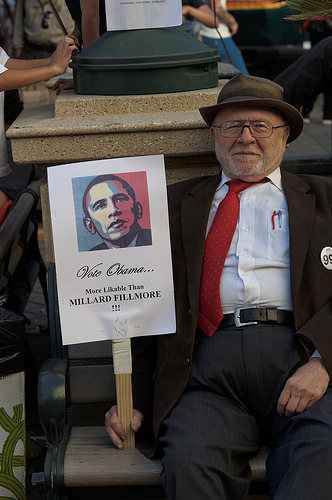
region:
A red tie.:
[195, 180, 251, 331]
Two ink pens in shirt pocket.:
[260, 199, 287, 247]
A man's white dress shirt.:
[212, 175, 290, 305]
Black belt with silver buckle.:
[217, 301, 291, 328]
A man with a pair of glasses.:
[200, 71, 304, 196]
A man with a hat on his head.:
[200, 63, 298, 182]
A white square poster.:
[40, 155, 178, 346]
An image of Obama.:
[66, 165, 161, 311]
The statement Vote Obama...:
[74, 261, 159, 279]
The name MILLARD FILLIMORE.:
[66, 288, 164, 306]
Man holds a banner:
[36, 65, 331, 498]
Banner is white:
[28, 149, 194, 471]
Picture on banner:
[59, 163, 159, 255]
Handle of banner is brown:
[102, 340, 149, 456]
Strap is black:
[221, 301, 292, 329]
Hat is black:
[186, 65, 305, 120]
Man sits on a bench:
[91, 66, 330, 499]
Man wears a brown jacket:
[61, 70, 330, 498]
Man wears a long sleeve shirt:
[84, 59, 331, 498]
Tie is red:
[198, 178, 249, 343]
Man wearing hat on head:
[200, 76, 311, 156]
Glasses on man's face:
[211, 118, 310, 160]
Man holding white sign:
[50, 136, 185, 442]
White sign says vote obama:
[35, 192, 194, 330]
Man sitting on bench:
[106, 354, 329, 470]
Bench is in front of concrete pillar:
[30, 176, 163, 377]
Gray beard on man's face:
[210, 124, 303, 186]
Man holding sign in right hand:
[101, 394, 169, 434]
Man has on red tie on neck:
[210, 166, 305, 333]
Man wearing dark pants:
[158, 385, 310, 488]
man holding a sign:
[105, 72, 331, 499]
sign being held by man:
[46, 153, 177, 345]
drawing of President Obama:
[71, 171, 152, 250]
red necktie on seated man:
[198, 178, 251, 340]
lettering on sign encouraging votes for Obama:
[68, 261, 163, 312]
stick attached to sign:
[112, 337, 137, 451]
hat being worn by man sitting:
[195, 72, 305, 145]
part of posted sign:
[104, 0, 188, 31]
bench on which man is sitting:
[43, 411, 165, 494]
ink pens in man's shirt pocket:
[268, 207, 283, 234]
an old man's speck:
[214, 113, 271, 137]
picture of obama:
[69, 172, 151, 255]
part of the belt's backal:
[233, 303, 280, 322]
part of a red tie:
[209, 222, 221, 282]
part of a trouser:
[233, 334, 265, 380]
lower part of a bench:
[72, 449, 127, 496]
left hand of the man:
[276, 363, 316, 411]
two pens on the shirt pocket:
[267, 207, 282, 226]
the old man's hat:
[220, 76, 298, 115]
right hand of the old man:
[91, 396, 144, 435]